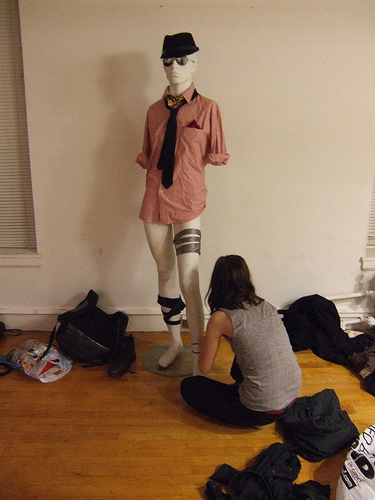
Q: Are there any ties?
A: Yes, there is a tie.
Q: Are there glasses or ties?
A: Yes, there is a tie.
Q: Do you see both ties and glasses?
A: Yes, there are both a tie and glasses.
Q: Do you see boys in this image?
A: No, there are no boys.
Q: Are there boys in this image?
A: No, there are no boys.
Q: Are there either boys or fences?
A: No, there are no boys or fences.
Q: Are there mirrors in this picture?
A: No, there are no mirrors.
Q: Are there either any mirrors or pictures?
A: No, there are no mirrors or pictures.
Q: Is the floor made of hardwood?
A: Yes, the floor is made of hardwood.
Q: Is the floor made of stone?
A: No, the floor is made of hardwood.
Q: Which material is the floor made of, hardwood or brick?
A: The floor is made of hardwood.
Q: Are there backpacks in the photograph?
A: Yes, there is a backpack.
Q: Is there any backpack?
A: Yes, there is a backpack.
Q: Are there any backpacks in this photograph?
A: Yes, there is a backpack.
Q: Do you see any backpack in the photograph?
A: Yes, there is a backpack.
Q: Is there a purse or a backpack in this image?
A: Yes, there is a backpack.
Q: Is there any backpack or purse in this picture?
A: Yes, there is a backpack.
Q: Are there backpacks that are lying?
A: Yes, there is a backpack that is lying.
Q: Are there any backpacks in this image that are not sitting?
A: Yes, there is a backpack that is lying.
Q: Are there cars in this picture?
A: No, there are no cars.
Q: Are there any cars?
A: No, there are no cars.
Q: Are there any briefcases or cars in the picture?
A: No, there are no cars or briefcases.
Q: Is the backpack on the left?
A: Yes, the backpack is on the left of the image.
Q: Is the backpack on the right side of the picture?
A: No, the backpack is on the left of the image.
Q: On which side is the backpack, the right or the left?
A: The backpack is on the left of the image.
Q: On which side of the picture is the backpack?
A: The backpack is on the left of the image.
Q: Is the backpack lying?
A: Yes, the backpack is lying.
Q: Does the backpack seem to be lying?
A: Yes, the backpack is lying.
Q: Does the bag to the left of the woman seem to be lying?
A: Yes, the backpack is lying.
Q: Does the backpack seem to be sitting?
A: No, the backpack is lying.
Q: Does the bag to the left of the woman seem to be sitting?
A: No, the backpack is lying.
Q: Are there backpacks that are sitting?
A: No, there is a backpack but it is lying.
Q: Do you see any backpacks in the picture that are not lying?
A: No, there is a backpack but it is lying.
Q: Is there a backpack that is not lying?
A: No, there is a backpack but it is lying.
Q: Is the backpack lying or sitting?
A: The backpack is lying.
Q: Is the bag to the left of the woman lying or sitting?
A: The backpack is lying.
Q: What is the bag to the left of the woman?
A: The bag is a backpack.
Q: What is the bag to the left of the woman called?
A: The bag is a backpack.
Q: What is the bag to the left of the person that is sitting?
A: The bag is a backpack.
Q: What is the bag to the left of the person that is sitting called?
A: The bag is a backpack.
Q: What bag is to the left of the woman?
A: The bag is a backpack.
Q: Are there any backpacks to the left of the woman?
A: Yes, there is a backpack to the left of the woman.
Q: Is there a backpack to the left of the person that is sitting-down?
A: Yes, there is a backpack to the left of the woman.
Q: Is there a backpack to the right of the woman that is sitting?
A: No, the backpack is to the left of the woman.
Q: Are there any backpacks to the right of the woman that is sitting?
A: No, the backpack is to the left of the woman.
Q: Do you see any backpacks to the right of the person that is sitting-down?
A: No, the backpack is to the left of the woman.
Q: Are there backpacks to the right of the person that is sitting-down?
A: No, the backpack is to the left of the woman.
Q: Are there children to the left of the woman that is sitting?
A: No, there is a backpack to the left of the woman.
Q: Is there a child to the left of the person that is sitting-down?
A: No, there is a backpack to the left of the woman.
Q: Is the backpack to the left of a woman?
A: Yes, the backpack is to the left of a woman.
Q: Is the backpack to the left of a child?
A: No, the backpack is to the left of a woman.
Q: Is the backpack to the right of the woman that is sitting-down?
A: No, the backpack is to the left of the woman.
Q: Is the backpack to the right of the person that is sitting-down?
A: No, the backpack is to the left of the woman.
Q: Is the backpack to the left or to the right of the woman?
A: The backpack is to the left of the woman.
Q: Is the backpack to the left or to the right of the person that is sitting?
A: The backpack is to the left of the woman.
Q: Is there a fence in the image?
A: No, there are no fences.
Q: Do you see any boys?
A: No, there are no boys.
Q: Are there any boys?
A: No, there are no boys.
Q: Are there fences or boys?
A: No, there are no boys or fences.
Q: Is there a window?
A: Yes, there is a window.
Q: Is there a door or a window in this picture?
A: Yes, there is a window.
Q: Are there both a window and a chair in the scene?
A: No, there is a window but no chairs.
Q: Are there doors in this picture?
A: No, there are no doors.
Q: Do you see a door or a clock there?
A: No, there are no doors or clocks.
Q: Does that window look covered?
A: Yes, the window is covered.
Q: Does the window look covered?
A: Yes, the window is covered.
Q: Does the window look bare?
A: No, the window is covered.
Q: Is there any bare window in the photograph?
A: No, there is a window but it is covered.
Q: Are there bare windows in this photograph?
A: No, there is a window but it is covered.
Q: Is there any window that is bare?
A: No, there is a window but it is covered.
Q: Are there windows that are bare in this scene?
A: No, there is a window but it is covered.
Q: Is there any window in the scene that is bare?
A: No, there is a window but it is covered.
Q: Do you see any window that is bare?
A: No, there is a window but it is covered.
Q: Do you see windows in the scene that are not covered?
A: No, there is a window but it is covered.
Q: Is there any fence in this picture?
A: No, there are no fences.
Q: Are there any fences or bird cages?
A: No, there are no fences or bird cages.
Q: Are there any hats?
A: Yes, there is a hat.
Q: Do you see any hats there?
A: Yes, there is a hat.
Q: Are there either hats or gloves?
A: Yes, there is a hat.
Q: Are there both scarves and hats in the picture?
A: No, there is a hat but no scarves.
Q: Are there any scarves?
A: No, there are no scarves.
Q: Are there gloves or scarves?
A: No, there are no scarves or gloves.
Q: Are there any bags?
A: Yes, there is a bag.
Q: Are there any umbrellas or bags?
A: Yes, there is a bag.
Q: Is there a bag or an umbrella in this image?
A: Yes, there is a bag.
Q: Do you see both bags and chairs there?
A: No, there is a bag but no chairs.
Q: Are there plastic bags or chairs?
A: Yes, there is a plastic bag.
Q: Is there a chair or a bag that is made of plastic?
A: Yes, the bag is made of plastic.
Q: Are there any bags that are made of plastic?
A: Yes, there is a bag that is made of plastic.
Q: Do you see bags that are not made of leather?
A: Yes, there is a bag that is made of plastic.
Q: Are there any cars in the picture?
A: No, there are no cars.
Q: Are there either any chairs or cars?
A: No, there are no cars or chairs.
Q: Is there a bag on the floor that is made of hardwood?
A: Yes, there is a bag on the floor.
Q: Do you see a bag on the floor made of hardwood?
A: Yes, there is a bag on the floor.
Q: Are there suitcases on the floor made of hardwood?
A: No, there is a bag on the floor.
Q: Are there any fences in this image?
A: No, there are no fences.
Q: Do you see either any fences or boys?
A: No, there are no fences or boys.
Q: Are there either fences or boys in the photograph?
A: No, there are no fences or boys.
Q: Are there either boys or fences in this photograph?
A: No, there are no fences or boys.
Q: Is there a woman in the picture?
A: Yes, there is a woman.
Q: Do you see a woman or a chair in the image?
A: Yes, there is a woman.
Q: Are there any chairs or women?
A: Yes, there is a woman.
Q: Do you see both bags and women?
A: Yes, there are both a woman and a bag.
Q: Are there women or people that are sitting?
A: Yes, the woman is sitting.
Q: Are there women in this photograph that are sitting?
A: Yes, there is a woman that is sitting.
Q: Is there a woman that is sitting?
A: Yes, there is a woman that is sitting.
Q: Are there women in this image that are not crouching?
A: Yes, there is a woman that is sitting.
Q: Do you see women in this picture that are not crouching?
A: Yes, there is a woman that is sitting .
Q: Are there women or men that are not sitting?
A: No, there is a woman but she is sitting.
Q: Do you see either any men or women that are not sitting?
A: No, there is a woman but she is sitting.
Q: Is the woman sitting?
A: Yes, the woman is sitting.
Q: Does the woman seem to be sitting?
A: Yes, the woman is sitting.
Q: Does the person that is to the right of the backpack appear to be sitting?
A: Yes, the woman is sitting.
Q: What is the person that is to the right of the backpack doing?
A: The woman is sitting.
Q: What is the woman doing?
A: The woman is sitting.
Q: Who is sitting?
A: The woman is sitting.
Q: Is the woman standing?
A: No, the woman is sitting.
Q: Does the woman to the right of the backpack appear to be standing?
A: No, the woman is sitting.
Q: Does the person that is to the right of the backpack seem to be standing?
A: No, the woman is sitting.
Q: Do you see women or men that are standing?
A: No, there is a woman but she is sitting.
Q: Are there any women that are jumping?
A: No, there is a woman but she is sitting.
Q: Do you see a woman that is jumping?
A: No, there is a woman but she is sitting.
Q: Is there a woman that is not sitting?
A: No, there is a woman but she is sitting.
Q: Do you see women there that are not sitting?
A: No, there is a woman but she is sitting.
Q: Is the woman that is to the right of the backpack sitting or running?
A: The woman is sitting.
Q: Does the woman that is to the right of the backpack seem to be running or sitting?
A: The woman is sitting.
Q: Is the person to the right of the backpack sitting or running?
A: The woman is sitting.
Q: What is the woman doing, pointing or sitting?
A: The woman is sitting.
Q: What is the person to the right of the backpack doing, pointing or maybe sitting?
A: The woman is sitting.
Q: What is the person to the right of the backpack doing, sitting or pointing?
A: The woman is sitting.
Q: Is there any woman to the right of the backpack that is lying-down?
A: Yes, there is a woman to the right of the backpack.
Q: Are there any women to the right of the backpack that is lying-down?
A: Yes, there is a woman to the right of the backpack.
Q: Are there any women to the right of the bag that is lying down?
A: Yes, there is a woman to the right of the backpack.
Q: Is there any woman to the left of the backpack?
A: No, the woman is to the right of the backpack.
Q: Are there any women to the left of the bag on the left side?
A: No, the woman is to the right of the backpack.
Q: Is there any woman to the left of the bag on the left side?
A: No, the woman is to the right of the backpack.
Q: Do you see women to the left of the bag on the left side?
A: No, the woman is to the right of the backpack.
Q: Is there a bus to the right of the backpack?
A: No, there is a woman to the right of the backpack.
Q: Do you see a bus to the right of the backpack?
A: No, there is a woman to the right of the backpack.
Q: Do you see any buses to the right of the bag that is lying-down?
A: No, there is a woman to the right of the backpack.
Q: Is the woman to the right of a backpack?
A: Yes, the woman is to the right of a backpack.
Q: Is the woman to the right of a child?
A: No, the woman is to the right of a backpack.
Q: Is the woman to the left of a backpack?
A: No, the woman is to the right of a backpack.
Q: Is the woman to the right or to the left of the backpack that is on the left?
A: The woman is to the right of the backpack.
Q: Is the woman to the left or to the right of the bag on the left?
A: The woman is to the right of the backpack.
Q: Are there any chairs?
A: No, there are no chairs.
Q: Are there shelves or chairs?
A: No, there are no chairs or shelves.